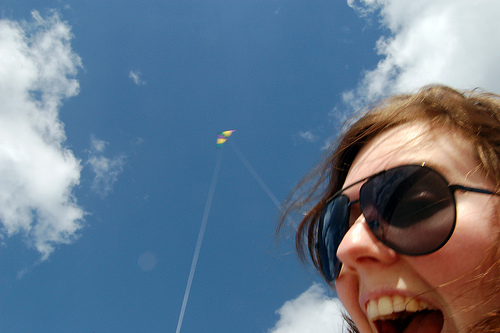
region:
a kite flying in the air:
[211, 128, 235, 148]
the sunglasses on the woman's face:
[305, 155, 499, 270]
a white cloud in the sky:
[351, 0, 498, 79]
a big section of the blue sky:
[86, 2, 349, 319]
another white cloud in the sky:
[2, 13, 86, 253]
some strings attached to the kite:
[172, 145, 309, 330]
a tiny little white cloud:
[271, 286, 346, 331]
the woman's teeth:
[356, 292, 434, 322]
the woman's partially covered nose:
[335, 224, 392, 271]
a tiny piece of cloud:
[122, 65, 147, 88]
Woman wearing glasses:
[300, 163, 499, 280]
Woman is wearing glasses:
[302, 158, 497, 282]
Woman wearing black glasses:
[302, 159, 498, 289]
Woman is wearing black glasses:
[297, 160, 496, 284]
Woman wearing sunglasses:
[302, 160, 495, 291]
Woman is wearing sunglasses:
[302, 155, 494, 281]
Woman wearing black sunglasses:
[301, 160, 496, 285]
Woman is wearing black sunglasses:
[305, 160, 499, 281]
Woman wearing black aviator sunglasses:
[305, 158, 498, 283]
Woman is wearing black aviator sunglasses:
[304, 159, 499, 279]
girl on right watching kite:
[298, 103, 495, 331]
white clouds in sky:
[362, 18, 497, 70]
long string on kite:
[187, 140, 227, 330]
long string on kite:
[230, 157, 300, 229]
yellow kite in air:
[212, 125, 233, 145]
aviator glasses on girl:
[310, 172, 465, 265]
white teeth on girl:
[360, 288, 428, 323]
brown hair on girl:
[350, 75, 492, 149]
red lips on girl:
[365, 280, 437, 304]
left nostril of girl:
[355, 250, 381, 267]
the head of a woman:
[278, 102, 496, 314]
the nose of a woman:
[297, 198, 418, 303]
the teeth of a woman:
[345, 266, 419, 327]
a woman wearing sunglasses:
[285, 132, 475, 273]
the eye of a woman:
[300, 163, 472, 255]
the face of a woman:
[330, 82, 478, 307]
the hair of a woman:
[291, 66, 492, 221]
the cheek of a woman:
[405, 193, 489, 293]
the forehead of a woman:
[322, 115, 476, 215]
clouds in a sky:
[17, 68, 201, 228]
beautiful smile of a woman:
[279, 79, 498, 327]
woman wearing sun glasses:
[286, 67, 498, 332]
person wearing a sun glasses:
[279, 71, 497, 328]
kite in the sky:
[191, 116, 245, 163]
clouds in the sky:
[0, 26, 101, 283]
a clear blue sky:
[187, 38, 289, 104]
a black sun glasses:
[288, 155, 498, 280]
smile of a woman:
[345, 278, 465, 331]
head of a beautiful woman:
[295, 92, 498, 327]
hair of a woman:
[279, 93, 358, 280]